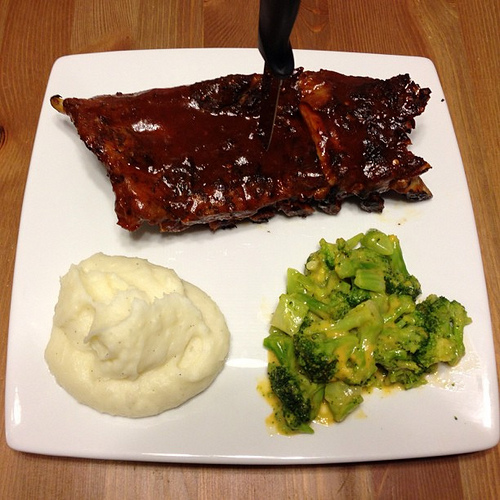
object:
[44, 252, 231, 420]
mashed potatoes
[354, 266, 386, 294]
broccoli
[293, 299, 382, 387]
broccoli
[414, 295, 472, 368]
broccoli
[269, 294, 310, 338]
broccoli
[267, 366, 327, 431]
broccoli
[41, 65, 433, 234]
ribs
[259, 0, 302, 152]
knife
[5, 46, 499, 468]
plate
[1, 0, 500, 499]
table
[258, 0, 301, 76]
handle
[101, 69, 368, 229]
sauce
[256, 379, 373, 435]
cheese sauce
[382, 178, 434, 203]
bones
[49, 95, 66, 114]
bone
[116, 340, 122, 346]
pepper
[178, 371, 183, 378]
pepper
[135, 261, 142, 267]
pepper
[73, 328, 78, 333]
pepper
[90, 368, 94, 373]
pepper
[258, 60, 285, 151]
blade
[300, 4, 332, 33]
knot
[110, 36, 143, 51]
knot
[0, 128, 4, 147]
knot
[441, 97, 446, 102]
speck